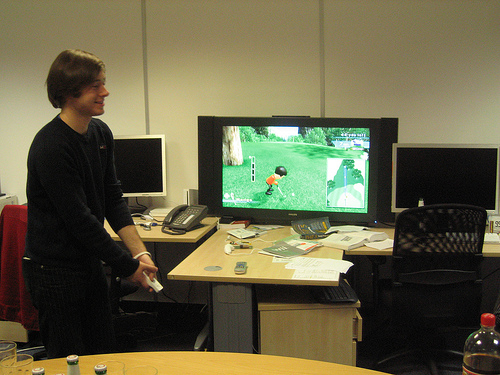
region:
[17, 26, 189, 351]
This is a person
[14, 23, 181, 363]
This is a woman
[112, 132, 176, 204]
This is a monitor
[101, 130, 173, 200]
This is a computer monitor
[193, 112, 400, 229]
This is a TV set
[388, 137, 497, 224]
This is a monitor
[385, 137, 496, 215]
This is a computer monitor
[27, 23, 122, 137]
head of a woman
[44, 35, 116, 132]
head of a lady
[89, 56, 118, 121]
Face of a woman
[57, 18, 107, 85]
man has brown hair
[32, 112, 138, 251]
man has black shirt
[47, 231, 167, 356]
man has black pants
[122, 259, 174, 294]
man has white controller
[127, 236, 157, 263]
white controller wristband on man's wrist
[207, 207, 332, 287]
brown and wooden table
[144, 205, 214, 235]
black telephone on table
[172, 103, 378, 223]
black LED tv on table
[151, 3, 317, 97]
tan wall behind tv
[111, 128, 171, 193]
black monitor is off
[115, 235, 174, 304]
Wii remote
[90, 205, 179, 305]
The man is holding the Wii remote with two hands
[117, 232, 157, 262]
The man has a white band around his wrist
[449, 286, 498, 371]
Bottle of coca cola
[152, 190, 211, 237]
Telephone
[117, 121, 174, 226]
Computer monitor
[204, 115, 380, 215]
TV playing a Wii golf game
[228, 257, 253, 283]
Cell phone on the table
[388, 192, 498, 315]
Black computer chair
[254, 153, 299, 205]
Wii golfer about to strike the golf ball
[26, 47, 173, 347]
Man Playing Nintendo Wii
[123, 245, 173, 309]
Hands Grasping white Game Controller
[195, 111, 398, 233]
Monitor Displaying a Golf Video Game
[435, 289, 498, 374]
Half Empty Bottle of Soda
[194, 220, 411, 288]
A Cluttered Top of a Desk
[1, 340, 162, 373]
Four Glasses with Three Green Bottles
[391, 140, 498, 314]
An Empty Chair Facing a Computer Monitor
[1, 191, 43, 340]
Red Jacket Covering the back of a Chair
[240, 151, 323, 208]
Animated Golfer Preparing to Swing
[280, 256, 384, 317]
Keyboard Partially Obscured by the Desk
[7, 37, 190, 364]
a boy holding a controller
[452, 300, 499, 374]
a bottle of soda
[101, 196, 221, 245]
a phone on the desk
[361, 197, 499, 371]
a black chair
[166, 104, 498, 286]
a television is on the desk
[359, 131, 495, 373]
a computer monitor is in front of the chair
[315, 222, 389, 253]
the book is open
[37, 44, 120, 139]
the boy has long brown hair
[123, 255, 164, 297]
the controller is white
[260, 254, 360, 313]
a black keyboard under the desk